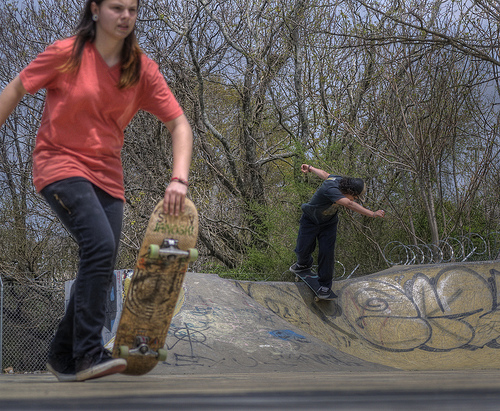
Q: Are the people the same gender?
A: No, they are both male and female.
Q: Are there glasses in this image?
A: No, there are no glasses.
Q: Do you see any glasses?
A: No, there are no glasses.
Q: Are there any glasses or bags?
A: No, there are no glasses or bags.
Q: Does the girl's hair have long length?
A: Yes, the hair is long.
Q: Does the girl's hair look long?
A: Yes, the hair is long.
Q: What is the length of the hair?
A: The hair is long.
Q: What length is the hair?
A: The hair is long.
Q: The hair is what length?
A: The hair is long.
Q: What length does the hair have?
A: The hair has long length.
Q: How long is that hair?
A: The hair is long.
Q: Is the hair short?
A: No, the hair is long.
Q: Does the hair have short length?
A: No, the hair is long.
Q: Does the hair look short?
A: No, the hair is long.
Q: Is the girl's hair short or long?
A: The hair is long.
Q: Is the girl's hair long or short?
A: The hair is long.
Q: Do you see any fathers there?
A: No, there are no fathers.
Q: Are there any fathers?
A: No, there are no fathers.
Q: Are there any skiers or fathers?
A: No, there are no fathers or skiers.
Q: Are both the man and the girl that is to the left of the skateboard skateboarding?
A: Yes, both the man and the girl are skateboarding.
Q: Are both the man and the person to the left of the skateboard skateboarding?
A: Yes, both the man and the girl are skateboarding.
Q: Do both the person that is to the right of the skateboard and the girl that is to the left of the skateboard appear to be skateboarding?
A: Yes, both the man and the girl are skateboarding.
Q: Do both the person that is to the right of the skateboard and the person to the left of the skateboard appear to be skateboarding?
A: Yes, both the man and the girl are skateboarding.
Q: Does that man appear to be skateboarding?
A: Yes, the man is skateboarding.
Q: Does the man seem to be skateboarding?
A: Yes, the man is skateboarding.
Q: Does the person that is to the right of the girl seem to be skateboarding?
A: Yes, the man is skateboarding.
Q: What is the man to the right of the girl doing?
A: The man is skateboarding.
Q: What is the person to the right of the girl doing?
A: The man is skateboarding.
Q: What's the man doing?
A: The man is skateboarding.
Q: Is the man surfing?
A: No, the man is skateboarding.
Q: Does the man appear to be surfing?
A: No, the man is skateboarding.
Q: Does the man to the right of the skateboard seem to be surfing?
A: No, the man is skateboarding.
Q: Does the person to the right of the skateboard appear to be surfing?
A: No, the man is skateboarding.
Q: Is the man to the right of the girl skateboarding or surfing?
A: The man is skateboarding.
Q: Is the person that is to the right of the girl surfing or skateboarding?
A: The man is skateboarding.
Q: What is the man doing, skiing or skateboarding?
A: The man is skateboarding.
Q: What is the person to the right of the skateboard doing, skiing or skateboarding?
A: The man is skateboarding.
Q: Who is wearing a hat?
A: The man is wearing a hat.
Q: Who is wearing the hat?
A: The man is wearing a hat.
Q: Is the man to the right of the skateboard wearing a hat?
A: Yes, the man is wearing a hat.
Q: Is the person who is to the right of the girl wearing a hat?
A: Yes, the man is wearing a hat.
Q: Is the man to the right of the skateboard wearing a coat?
A: No, the man is wearing a hat.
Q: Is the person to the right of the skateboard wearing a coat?
A: No, the man is wearing a hat.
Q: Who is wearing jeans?
A: The man is wearing jeans.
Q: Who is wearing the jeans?
A: The man is wearing jeans.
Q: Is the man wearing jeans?
A: Yes, the man is wearing jeans.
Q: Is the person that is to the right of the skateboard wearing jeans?
A: Yes, the man is wearing jeans.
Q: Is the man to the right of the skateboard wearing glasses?
A: No, the man is wearing jeans.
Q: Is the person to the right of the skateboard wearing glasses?
A: No, the man is wearing jeans.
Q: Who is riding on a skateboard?
A: The man is riding on a skateboard.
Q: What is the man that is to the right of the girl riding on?
A: The man is riding on a skateboard.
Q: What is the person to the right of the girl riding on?
A: The man is riding on a skateboard.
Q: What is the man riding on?
A: The man is riding on a skateboard.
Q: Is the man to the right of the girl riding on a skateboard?
A: Yes, the man is riding on a skateboard.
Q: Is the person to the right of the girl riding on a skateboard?
A: Yes, the man is riding on a skateboard.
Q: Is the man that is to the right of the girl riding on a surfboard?
A: No, the man is riding on a skateboard.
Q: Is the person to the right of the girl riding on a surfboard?
A: No, the man is riding on a skateboard.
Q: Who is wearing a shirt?
A: The man is wearing a shirt.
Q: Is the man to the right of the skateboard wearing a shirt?
A: Yes, the man is wearing a shirt.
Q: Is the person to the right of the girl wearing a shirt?
A: Yes, the man is wearing a shirt.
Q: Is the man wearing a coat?
A: No, the man is wearing a shirt.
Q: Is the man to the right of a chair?
A: No, the man is to the right of the skateboard.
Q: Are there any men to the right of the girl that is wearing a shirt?
A: Yes, there is a man to the right of the girl.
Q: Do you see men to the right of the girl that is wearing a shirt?
A: Yes, there is a man to the right of the girl.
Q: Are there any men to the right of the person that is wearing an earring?
A: Yes, there is a man to the right of the girl.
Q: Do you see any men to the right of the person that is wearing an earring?
A: Yes, there is a man to the right of the girl.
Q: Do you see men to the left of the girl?
A: No, the man is to the right of the girl.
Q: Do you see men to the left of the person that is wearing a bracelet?
A: No, the man is to the right of the girl.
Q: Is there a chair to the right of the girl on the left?
A: No, there is a man to the right of the girl.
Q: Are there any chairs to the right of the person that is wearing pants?
A: No, there is a man to the right of the girl.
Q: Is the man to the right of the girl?
A: Yes, the man is to the right of the girl.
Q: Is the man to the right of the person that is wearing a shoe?
A: Yes, the man is to the right of the girl.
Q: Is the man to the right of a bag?
A: No, the man is to the right of the girl.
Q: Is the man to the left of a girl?
A: No, the man is to the right of a girl.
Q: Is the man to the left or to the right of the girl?
A: The man is to the right of the girl.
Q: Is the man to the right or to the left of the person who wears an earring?
A: The man is to the right of the girl.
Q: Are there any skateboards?
A: Yes, there is a skateboard.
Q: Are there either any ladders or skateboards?
A: Yes, there is a skateboard.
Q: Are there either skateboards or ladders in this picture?
A: Yes, there is a skateboard.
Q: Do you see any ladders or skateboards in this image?
A: Yes, there is a skateboard.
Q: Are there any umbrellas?
A: No, there are no umbrellas.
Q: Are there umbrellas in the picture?
A: No, there are no umbrellas.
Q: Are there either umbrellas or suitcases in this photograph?
A: No, there are no umbrellas or suitcases.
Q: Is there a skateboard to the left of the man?
A: Yes, there is a skateboard to the left of the man.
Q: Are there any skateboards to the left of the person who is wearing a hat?
A: Yes, there is a skateboard to the left of the man.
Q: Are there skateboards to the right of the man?
A: No, the skateboard is to the left of the man.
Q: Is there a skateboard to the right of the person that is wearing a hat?
A: No, the skateboard is to the left of the man.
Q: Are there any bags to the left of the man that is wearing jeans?
A: No, there is a skateboard to the left of the man.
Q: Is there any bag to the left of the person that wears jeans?
A: No, there is a skateboard to the left of the man.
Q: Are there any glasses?
A: No, there are no glasses.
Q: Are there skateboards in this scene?
A: Yes, there is a skateboard.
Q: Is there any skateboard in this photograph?
A: Yes, there is a skateboard.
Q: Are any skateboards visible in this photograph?
A: Yes, there is a skateboard.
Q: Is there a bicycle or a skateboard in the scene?
A: Yes, there is a skateboard.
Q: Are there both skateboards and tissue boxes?
A: No, there is a skateboard but no tissue boxes.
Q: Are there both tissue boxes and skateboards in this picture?
A: No, there is a skateboard but no tissue boxes.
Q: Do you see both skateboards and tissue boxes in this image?
A: No, there is a skateboard but no tissue boxes.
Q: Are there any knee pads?
A: No, there are no knee pads.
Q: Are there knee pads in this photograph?
A: No, there are no knee pads.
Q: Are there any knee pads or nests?
A: No, there are no knee pads or nests.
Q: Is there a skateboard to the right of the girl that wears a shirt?
A: Yes, there is a skateboard to the right of the girl.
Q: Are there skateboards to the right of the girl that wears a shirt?
A: Yes, there is a skateboard to the right of the girl.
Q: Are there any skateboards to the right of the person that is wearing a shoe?
A: Yes, there is a skateboard to the right of the girl.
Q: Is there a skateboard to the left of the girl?
A: No, the skateboard is to the right of the girl.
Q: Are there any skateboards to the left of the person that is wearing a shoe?
A: No, the skateboard is to the right of the girl.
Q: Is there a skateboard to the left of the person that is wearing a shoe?
A: No, the skateboard is to the right of the girl.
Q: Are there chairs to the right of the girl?
A: No, there is a skateboard to the right of the girl.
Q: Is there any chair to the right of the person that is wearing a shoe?
A: No, there is a skateboard to the right of the girl.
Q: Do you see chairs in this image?
A: No, there are no chairs.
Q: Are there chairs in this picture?
A: No, there are no chairs.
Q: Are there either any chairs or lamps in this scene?
A: No, there are no chairs or lamps.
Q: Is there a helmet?
A: No, there are no helmets.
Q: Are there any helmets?
A: No, there are no helmets.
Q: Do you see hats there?
A: Yes, there is a hat.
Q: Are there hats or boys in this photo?
A: Yes, there is a hat.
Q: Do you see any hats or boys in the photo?
A: Yes, there is a hat.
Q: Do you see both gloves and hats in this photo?
A: No, there is a hat but no gloves.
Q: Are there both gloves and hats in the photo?
A: No, there is a hat but no gloves.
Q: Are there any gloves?
A: No, there are no gloves.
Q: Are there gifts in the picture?
A: No, there are no gifts.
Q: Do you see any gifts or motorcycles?
A: No, there are no gifts or motorcycles.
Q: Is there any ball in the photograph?
A: No, there are no balls.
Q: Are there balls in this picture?
A: No, there are no balls.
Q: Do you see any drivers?
A: No, there are no drivers.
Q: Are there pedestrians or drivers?
A: No, there are no drivers or pedestrians.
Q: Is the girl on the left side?
A: Yes, the girl is on the left of the image.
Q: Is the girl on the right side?
A: No, the girl is on the left of the image.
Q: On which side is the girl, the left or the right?
A: The girl is on the left of the image.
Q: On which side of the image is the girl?
A: The girl is on the left of the image.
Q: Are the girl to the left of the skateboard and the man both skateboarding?
A: Yes, both the girl and the man are skateboarding.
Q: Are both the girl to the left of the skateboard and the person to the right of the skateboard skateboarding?
A: Yes, both the girl and the man are skateboarding.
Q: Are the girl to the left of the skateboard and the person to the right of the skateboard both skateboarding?
A: Yes, both the girl and the man are skateboarding.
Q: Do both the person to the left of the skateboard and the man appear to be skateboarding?
A: Yes, both the girl and the man are skateboarding.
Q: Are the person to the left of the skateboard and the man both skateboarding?
A: Yes, both the girl and the man are skateboarding.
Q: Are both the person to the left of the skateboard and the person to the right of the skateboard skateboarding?
A: Yes, both the girl and the man are skateboarding.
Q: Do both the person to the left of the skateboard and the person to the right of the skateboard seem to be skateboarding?
A: Yes, both the girl and the man are skateboarding.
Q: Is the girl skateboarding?
A: Yes, the girl is skateboarding.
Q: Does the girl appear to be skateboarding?
A: Yes, the girl is skateboarding.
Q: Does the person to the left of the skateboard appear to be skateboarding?
A: Yes, the girl is skateboarding.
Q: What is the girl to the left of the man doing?
A: The girl is skateboarding.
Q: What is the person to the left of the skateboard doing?
A: The girl is skateboarding.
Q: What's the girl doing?
A: The girl is skateboarding.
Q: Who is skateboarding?
A: The girl is skateboarding.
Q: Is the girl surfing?
A: No, the girl is skateboarding.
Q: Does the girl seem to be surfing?
A: No, the girl is skateboarding.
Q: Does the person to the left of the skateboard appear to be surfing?
A: No, the girl is skateboarding.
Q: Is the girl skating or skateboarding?
A: The girl is skateboarding.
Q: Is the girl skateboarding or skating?
A: The girl is skateboarding.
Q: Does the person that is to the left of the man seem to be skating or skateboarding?
A: The girl is skateboarding.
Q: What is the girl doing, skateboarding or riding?
A: The girl is skateboarding.